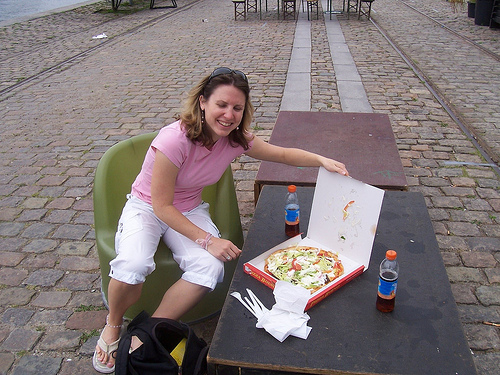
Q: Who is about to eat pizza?
A: This woman.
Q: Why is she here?
A: To eat pizza.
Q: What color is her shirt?
A: Pink.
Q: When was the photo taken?
A: Daylight hours.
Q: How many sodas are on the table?
A: Two.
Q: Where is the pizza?
A: On the table.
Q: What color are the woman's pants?
A: White.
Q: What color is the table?
A: Black.